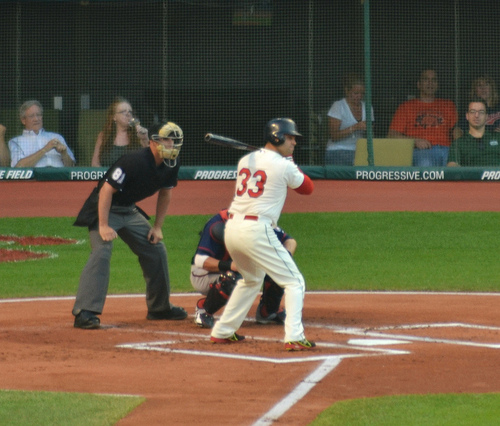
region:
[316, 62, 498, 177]
fans sitting behind the fence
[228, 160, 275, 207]
33 on the shirt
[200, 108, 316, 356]
player holding the bat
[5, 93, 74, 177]
man with white shirt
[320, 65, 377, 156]
woman texting on her cell phone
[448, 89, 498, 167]
man wearing glasses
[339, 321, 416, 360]
white stripes on the field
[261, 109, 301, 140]
helmet on the mans head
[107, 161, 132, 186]
number 8 on the shirt sleeve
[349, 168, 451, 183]
progressive.com banner on the fence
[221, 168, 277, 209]
33 is red in color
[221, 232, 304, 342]
the pants are white in color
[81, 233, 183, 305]
the apnts are grey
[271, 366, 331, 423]
the line is white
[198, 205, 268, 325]
the guy is crouching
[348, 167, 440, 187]
progressive is the sponsor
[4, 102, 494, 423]
the game is baseball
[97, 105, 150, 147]
the woman is drinking wine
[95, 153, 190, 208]
the shirt is black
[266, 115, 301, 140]
the helmet is black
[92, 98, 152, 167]
Woman drinking a beverage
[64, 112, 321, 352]
Three baseball players on the field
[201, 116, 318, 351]
Baseball player getting ready to swing a bat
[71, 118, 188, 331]
Man wearing yellow helmet and black clothing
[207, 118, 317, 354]
Man wearing a white baseball uniform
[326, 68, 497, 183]
People watching a baseball game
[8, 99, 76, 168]
Older man in white button down shirt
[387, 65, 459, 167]
Man wearing an orange t-shirt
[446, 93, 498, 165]
Man in glasses wearing a green shirt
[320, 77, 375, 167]
Woman looking at her cellphone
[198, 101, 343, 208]
a man holding a baseball bat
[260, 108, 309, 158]
a man wearing a helmet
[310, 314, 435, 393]
home plate on a baseball field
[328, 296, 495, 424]
white chalk lines on a baseball field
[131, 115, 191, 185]
a man wearing a safety mask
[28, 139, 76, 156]
a man holding his hands together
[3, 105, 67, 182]
a man wearing a white shirt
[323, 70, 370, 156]
a woman wearing a white shirt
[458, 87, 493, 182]
a man wearing a green shirt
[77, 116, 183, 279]
a man bent over with his hand on his knees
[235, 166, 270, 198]
red number print on the back of a shirt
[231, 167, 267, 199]
red 33 print on the back of a shirt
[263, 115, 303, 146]
black helmet on a baseball player's head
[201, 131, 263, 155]
black bat in a baseball player's hands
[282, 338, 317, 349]
multicolored cleats on a baseball player's foot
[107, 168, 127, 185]
81 print on an umpire's shirt sleeve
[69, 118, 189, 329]
umpire on a baseball field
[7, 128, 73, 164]
white button down shirt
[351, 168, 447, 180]
website adress advertisement print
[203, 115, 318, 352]
baseball player preparing to swing his bat